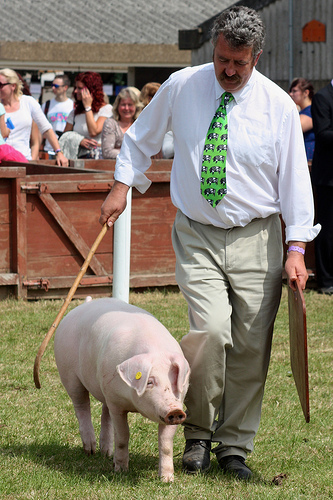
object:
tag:
[134, 369, 143, 379]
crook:
[33, 353, 41, 390]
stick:
[33, 221, 109, 389]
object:
[301, 18, 326, 42]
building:
[175, 0, 331, 95]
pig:
[54, 296, 192, 482]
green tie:
[200, 92, 234, 209]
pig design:
[206, 177, 218, 187]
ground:
[0, 286, 332, 497]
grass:
[0, 281, 332, 498]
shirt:
[113, 62, 322, 243]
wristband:
[287, 245, 306, 253]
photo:
[0, 0, 332, 394]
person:
[101, 88, 143, 160]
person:
[288, 78, 315, 176]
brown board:
[287, 267, 310, 423]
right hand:
[283, 252, 310, 290]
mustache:
[217, 71, 242, 81]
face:
[213, 35, 252, 91]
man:
[40, 74, 75, 160]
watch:
[83, 105, 92, 112]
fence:
[0, 164, 179, 302]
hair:
[210, 5, 265, 67]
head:
[211, 5, 266, 93]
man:
[99, 5, 321, 482]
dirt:
[185, 453, 200, 466]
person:
[0, 67, 69, 169]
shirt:
[0, 94, 53, 160]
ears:
[116, 352, 155, 397]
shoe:
[181, 437, 211, 472]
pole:
[111, 186, 133, 304]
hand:
[98, 187, 127, 228]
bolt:
[23, 277, 50, 288]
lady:
[63, 72, 114, 160]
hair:
[72, 72, 105, 117]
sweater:
[57, 130, 84, 160]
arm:
[64, 122, 85, 147]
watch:
[54, 149, 62, 154]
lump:
[270, 471, 287, 486]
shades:
[49, 82, 68, 89]